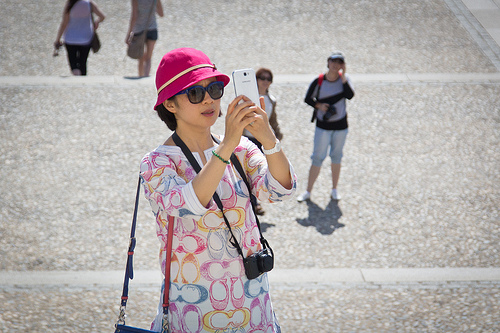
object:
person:
[296, 52, 355, 203]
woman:
[139, 46, 297, 333]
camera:
[232, 68, 263, 110]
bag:
[113, 151, 179, 332]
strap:
[118, 151, 184, 313]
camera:
[243, 248, 275, 279]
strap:
[170, 130, 275, 257]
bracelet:
[212, 150, 231, 165]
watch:
[261, 138, 281, 155]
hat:
[153, 47, 230, 111]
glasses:
[168, 81, 224, 104]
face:
[163, 75, 226, 126]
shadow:
[295, 196, 346, 235]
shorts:
[309, 126, 348, 166]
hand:
[225, 94, 259, 144]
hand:
[243, 95, 277, 143]